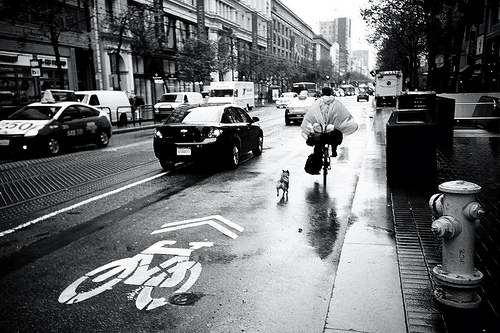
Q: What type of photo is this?
A: Black and white.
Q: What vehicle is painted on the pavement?
A: Bicycle.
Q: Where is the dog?
A: In the street.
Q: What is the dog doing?
A: Running.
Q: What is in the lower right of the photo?
A: Fire hydrant.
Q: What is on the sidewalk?
A: A fire hydrant.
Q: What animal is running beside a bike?
A: A dog.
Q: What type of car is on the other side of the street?
A: A taxicab.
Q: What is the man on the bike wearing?
A: A raincoat.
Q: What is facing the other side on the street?
A: A saloon car.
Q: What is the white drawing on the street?
A: A drawing of a bike.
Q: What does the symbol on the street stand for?
A: A bike lane.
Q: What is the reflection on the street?
A: The person on the bike.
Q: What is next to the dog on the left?
A: A car.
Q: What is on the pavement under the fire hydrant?
A: Bricks.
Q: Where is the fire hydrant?
A: On the sidewalk.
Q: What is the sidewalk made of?
A: Bricks.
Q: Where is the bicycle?
A: In the bike lane.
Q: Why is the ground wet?
A: Rain.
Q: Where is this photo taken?
A: City.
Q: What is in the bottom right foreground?
A: Fire Hydrant.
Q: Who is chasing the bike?
A: A dog.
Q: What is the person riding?
A: A bike.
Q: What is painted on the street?
A: A bicycle lane sign.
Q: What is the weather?
A: Rainy.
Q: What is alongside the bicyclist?
A: A car.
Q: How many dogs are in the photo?
A: One.